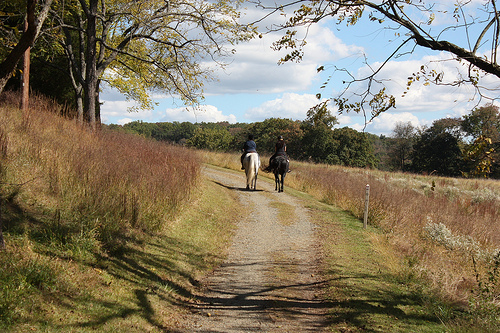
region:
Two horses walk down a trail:
[228, 126, 314, 208]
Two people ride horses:
[223, 116, 301, 208]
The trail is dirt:
[176, 141, 332, 316]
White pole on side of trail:
[353, 173, 379, 236]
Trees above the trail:
[246, 3, 476, 126]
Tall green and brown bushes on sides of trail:
[18, 86, 211, 317]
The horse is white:
[234, 127, 264, 190]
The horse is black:
[266, 132, 308, 203]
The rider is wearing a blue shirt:
[233, 128, 271, 195]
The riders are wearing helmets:
[229, 120, 291, 195]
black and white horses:
[233, 147, 292, 197]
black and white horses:
[219, 150, 310, 209]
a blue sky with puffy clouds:
[95, 0, 498, 143]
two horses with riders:
[233, 122, 292, 194]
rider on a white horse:
[231, 130, 256, 195]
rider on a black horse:
[265, 130, 291, 195]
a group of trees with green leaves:
[0, 1, 257, 143]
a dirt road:
[189, 158, 333, 330]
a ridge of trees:
[108, 111, 498, 183]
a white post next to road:
[357, 177, 375, 231]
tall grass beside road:
[1, 81, 211, 331]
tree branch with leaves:
[255, 0, 498, 132]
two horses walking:
[235, 133, 292, 193]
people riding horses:
[241, 134, 291, 191]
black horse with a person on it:
[266, 134, 295, 195]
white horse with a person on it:
[241, 134, 263, 191]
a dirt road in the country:
[163, 185, 344, 331]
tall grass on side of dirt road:
[16, 100, 241, 245]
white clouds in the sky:
[188, 20, 343, 111]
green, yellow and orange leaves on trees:
[131, 112, 397, 167]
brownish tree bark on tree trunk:
[79, 7, 104, 124]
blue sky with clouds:
[101, 2, 498, 128]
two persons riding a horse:
[228, 122, 306, 196]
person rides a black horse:
[266, 129, 299, 198]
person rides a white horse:
[237, 127, 266, 197]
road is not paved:
[178, 152, 345, 332]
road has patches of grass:
[160, 170, 317, 301]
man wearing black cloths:
[264, 126, 294, 198]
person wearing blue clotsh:
[237, 128, 264, 158]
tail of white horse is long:
[245, 152, 257, 191]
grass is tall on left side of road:
[18, 101, 213, 237]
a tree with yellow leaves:
[14, 0, 234, 122]